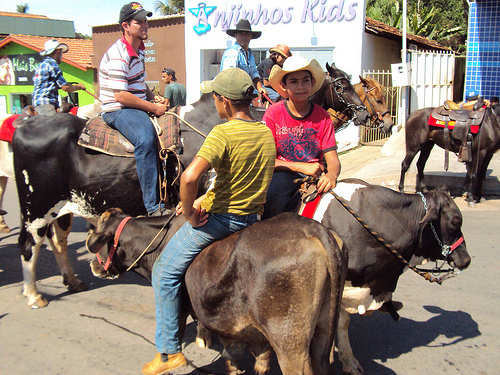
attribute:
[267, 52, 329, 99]
cowboy hat — beige, black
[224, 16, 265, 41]
cowboy hat — black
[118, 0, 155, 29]
baseball cap — black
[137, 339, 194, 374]
boot — brown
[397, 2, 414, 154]
pole — white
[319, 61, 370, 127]
horse's head — dark brown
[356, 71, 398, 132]
horse's head — light brown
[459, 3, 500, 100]
wall — blue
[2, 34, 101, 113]
building — green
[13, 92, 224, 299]
cow — black, white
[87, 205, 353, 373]
cow — brown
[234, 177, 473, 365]
cow — black, white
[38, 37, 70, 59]
cowboy hat — white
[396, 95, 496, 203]
horse — brown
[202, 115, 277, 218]
shirt — yellow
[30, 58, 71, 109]
shirt — blue, white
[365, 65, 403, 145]
fence — white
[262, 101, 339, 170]
shirt — red